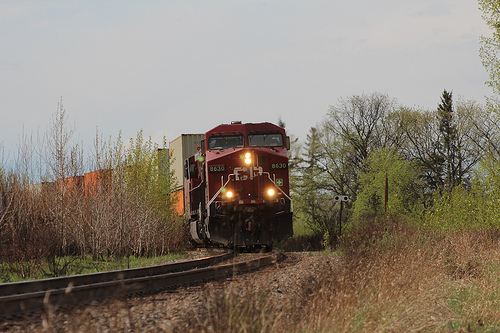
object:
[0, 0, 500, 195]
clouds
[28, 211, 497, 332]
dying grass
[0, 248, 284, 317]
tracks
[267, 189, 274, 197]
headlights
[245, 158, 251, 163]
headlights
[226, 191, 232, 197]
headlights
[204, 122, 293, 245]
engine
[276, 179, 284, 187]
sign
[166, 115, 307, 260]
train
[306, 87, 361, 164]
wall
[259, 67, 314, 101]
ground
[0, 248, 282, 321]
railroad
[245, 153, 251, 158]
headlight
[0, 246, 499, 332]
area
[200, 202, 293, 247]
guard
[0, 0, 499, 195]
sky